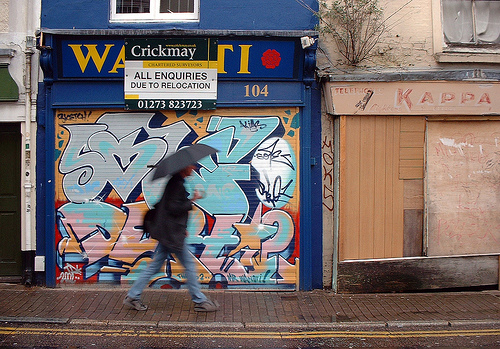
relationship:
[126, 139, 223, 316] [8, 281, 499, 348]
person walking on sidewalk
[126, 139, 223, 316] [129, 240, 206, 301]
person wearing jeans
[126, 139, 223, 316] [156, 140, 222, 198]
person holding umbrella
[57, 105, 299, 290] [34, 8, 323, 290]
graffiti on building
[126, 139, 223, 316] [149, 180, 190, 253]
person wearing jacket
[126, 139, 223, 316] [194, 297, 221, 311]
person wearing shoe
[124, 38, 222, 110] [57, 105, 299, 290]
sign over graffiti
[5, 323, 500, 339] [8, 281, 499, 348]
line on sidewalk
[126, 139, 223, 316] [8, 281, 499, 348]
person walking down sidewalk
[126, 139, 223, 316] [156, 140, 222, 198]
person holding an umbrella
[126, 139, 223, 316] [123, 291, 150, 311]
person wearing shoe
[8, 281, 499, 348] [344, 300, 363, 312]
sidewalk made of brick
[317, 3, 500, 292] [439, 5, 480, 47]
building has panel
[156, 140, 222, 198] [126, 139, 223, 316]
umbrella on person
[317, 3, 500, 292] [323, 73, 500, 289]
building has wall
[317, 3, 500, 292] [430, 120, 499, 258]
building has door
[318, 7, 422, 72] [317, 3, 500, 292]
tree on building